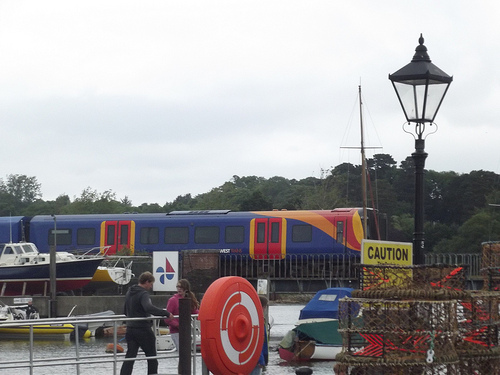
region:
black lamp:
[380, 11, 469, 276]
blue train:
[8, 205, 383, 312]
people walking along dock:
[114, 272, 216, 362]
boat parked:
[4, 231, 121, 300]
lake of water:
[0, 328, 354, 373]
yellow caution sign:
[357, 226, 439, 322]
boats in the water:
[2, 292, 386, 374]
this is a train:
[0, 169, 395, 298]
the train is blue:
[21, 195, 406, 298]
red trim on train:
[320, 201, 362, 253]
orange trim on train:
[274, 203, 345, 243]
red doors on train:
[231, 206, 308, 272]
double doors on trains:
[228, 207, 310, 272]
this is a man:
[111, 262, 173, 373]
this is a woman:
[161, 264, 206, 373]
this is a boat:
[0, 214, 128, 339]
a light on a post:
[373, 15, 488, 364]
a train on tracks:
[83, 160, 436, 318]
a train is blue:
[56, 168, 413, 279]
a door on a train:
[251, 216, 285, 262]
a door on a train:
[99, 215, 137, 263]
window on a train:
[164, 225, 185, 245]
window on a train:
[193, 225, 219, 247]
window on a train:
[226, 223, 245, 243]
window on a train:
[291, 227, 313, 241]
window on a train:
[76, 227, 99, 250]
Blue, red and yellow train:
[0, 206, 380, 284]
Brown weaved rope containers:
[336, 240, 498, 373]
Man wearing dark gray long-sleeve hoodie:
[117, 270, 169, 370]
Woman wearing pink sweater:
[165, 275, 200, 370]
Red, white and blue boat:
[0, 210, 110, 291]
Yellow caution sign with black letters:
[360, 235, 415, 291]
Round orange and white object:
[195, 275, 262, 371]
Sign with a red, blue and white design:
[150, 250, 176, 290]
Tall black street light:
[385, 30, 450, 280]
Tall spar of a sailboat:
[336, 75, 381, 263]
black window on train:
[42, 221, 75, 251]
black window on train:
[70, 225, 100, 255]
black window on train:
[106, 219, 113, 251]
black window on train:
[116, 224, 133, 249]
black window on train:
[138, 221, 162, 244]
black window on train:
[161, 224, 191, 249]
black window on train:
[194, 225, 221, 247]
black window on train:
[222, 217, 252, 249]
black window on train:
[252, 219, 266, 251]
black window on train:
[268, 219, 282, 249]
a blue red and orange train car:
[27, 205, 384, 281]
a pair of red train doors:
[253, 216, 282, 262]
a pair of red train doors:
[103, 218, 130, 260]